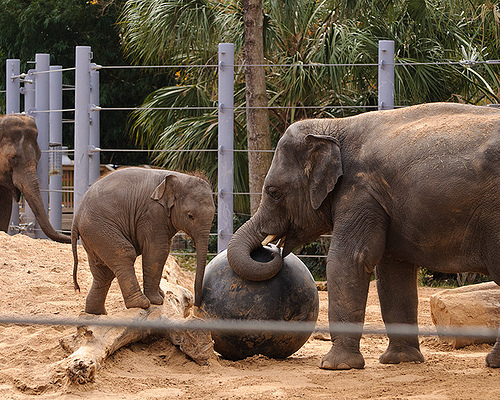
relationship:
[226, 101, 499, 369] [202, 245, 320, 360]
elephant playing with ball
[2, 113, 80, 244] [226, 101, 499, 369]
elephant watching elephant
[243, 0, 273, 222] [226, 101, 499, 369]
trunk behind elephant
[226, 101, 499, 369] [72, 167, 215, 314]
elephant next to elephant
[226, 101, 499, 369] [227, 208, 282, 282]
elephant with curled trunk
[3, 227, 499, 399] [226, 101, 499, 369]
dirt under elephant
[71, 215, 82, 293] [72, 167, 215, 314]
tail on elephant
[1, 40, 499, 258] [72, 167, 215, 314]
fence behind elephant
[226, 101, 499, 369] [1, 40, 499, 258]
elephant inside fence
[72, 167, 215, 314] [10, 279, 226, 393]
elephant on log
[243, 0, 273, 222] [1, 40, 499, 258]
trunk outside fence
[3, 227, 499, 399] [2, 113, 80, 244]
dirt under elephant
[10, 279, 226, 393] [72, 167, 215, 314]
log under elephant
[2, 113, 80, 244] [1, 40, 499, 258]
elephant next to fence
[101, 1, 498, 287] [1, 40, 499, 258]
palm trees behind fence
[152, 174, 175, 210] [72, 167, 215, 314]
ear of elephant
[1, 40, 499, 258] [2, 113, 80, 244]
fence around elephant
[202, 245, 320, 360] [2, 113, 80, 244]
ball next to elephant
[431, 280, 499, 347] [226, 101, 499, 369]
rock behind elephant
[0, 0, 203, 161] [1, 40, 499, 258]
trees outside fence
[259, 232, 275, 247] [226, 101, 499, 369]
tusk on elephant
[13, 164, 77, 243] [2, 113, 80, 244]
trunk on elephant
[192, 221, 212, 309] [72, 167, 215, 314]
trunk of elephant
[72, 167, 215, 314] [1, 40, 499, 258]
elephant inside fence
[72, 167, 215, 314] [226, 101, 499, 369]
elephant next to elephant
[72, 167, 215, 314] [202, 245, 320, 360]
elephant pushing ball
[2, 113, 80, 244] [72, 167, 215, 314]
elephant behind elephant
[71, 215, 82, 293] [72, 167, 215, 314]
tail of elephant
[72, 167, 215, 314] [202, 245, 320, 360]
elephant playing with ball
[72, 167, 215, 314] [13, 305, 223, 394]
elephant standing on wood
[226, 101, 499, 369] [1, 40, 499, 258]
elephant caged in fence